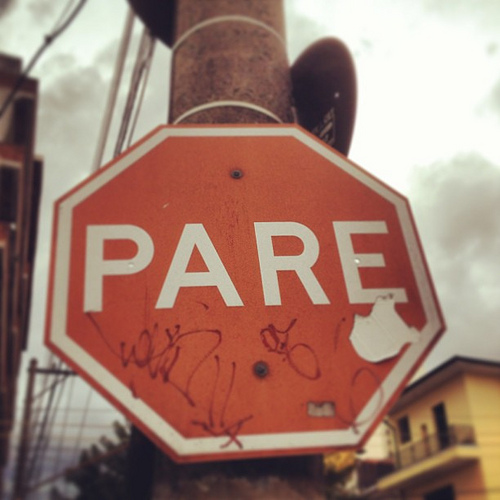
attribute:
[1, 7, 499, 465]
residential area — closeup, exterior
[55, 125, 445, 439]
sign — close, angled, red, attached, octaganol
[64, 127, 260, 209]
borders — white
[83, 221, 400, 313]
letters — white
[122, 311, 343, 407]
graffiti — illegible, purple, scribbled, black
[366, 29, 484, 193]
sky — milky white, cloudy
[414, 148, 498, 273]
clouds — grey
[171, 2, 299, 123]
pole — brown, rusty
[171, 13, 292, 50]
circles — white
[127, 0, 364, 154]
signs — showing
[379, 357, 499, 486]
building — yellow, tan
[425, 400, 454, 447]
door — dark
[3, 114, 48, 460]
building — tall, red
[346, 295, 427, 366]
spot — white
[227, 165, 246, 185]
screw — holding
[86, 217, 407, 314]
pare — white, written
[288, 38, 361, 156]
sign — round, hanging